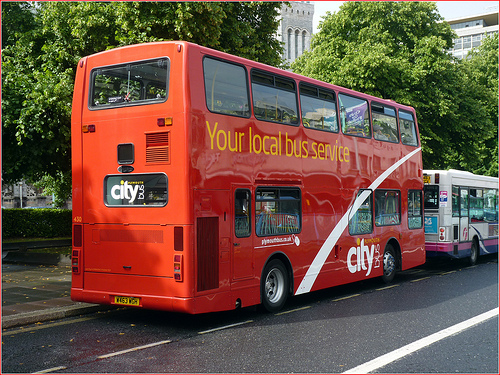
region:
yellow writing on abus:
[201, 131, 370, 171]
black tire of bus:
[242, 242, 302, 321]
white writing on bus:
[327, 229, 382, 286]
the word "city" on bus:
[314, 233, 390, 290]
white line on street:
[393, 304, 490, 372]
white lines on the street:
[136, 321, 246, 373]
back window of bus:
[93, 165, 170, 221]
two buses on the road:
[368, 174, 493, 272]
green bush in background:
[4, 201, 59, 253]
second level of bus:
[132, 78, 427, 190]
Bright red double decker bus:
[69, 40, 431, 317]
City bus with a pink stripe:
[423, 164, 498, 265]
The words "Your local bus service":
[202, 118, 352, 165]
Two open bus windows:
[245, 63, 341, 136]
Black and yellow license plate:
[112, 292, 141, 308]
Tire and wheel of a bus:
[258, 252, 294, 313]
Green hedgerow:
[0, 204, 74, 242]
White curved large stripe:
[289, 144, 424, 295]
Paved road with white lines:
[1, 260, 499, 374]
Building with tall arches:
[269, 1, 313, 73]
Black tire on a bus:
[247, 249, 307, 314]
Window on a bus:
[211, 169, 326, 253]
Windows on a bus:
[338, 173, 430, 243]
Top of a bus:
[64, 48, 470, 230]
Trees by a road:
[4, 6, 150, 268]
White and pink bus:
[418, 147, 498, 263]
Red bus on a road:
[47, 26, 427, 318]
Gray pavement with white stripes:
[388, 283, 498, 368]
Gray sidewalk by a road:
[18, 273, 78, 367]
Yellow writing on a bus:
[188, 109, 403, 171]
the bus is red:
[40, 47, 434, 282]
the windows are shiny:
[196, 67, 428, 168]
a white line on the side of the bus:
[307, 124, 414, 319]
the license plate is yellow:
[90, 283, 156, 324]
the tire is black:
[232, 255, 294, 306]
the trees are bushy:
[312, 1, 473, 161]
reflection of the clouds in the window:
[197, 93, 395, 145]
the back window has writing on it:
[81, 157, 176, 218]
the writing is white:
[64, 170, 161, 207]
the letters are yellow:
[197, 107, 370, 156]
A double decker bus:
[63, 47, 435, 302]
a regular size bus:
[424, 157, 499, 276]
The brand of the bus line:
[335, 237, 399, 274]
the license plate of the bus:
[105, 285, 160, 325]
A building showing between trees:
[263, 0, 314, 74]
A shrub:
[0, 203, 74, 254]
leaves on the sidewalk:
[0, 257, 71, 357]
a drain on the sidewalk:
[0, 277, 64, 303]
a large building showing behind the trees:
[436, 14, 498, 69]